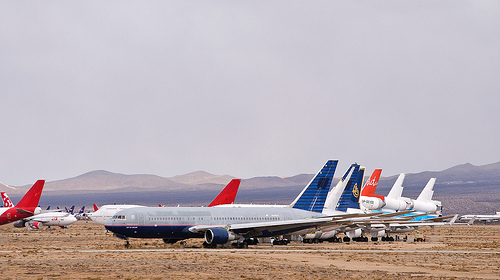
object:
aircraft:
[103, 158, 442, 249]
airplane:
[103, 159, 384, 250]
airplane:
[74, 206, 87, 221]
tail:
[289, 159, 383, 225]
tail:
[338, 167, 367, 214]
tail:
[359, 168, 386, 210]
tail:
[386, 173, 415, 212]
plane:
[89, 178, 241, 224]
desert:
[1, 251, 41, 278]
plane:
[212, 162, 386, 244]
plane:
[381, 172, 414, 241]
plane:
[410, 177, 458, 230]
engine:
[204, 227, 229, 245]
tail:
[207, 178, 241, 207]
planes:
[458, 211, 499, 225]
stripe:
[372, 209, 437, 221]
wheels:
[238, 243, 248, 249]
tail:
[288, 159, 338, 213]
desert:
[261, 247, 360, 270]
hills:
[79, 169, 209, 204]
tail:
[16, 179, 46, 214]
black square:
[317, 178, 329, 189]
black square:
[344, 180, 352, 191]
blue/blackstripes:
[288, 159, 339, 213]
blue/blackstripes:
[334, 162, 364, 213]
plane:
[0, 179, 78, 231]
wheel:
[123, 240, 130, 250]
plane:
[358, 168, 416, 242]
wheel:
[381, 236, 385, 241]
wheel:
[343, 237, 351, 242]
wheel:
[303, 238, 313, 243]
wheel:
[284, 240, 288, 245]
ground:
[251, 189, 291, 204]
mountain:
[380, 158, 498, 190]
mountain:
[240, 171, 313, 195]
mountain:
[0, 169, 118, 197]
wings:
[188, 216, 343, 238]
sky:
[225, 46, 316, 90]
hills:
[438, 162, 497, 190]